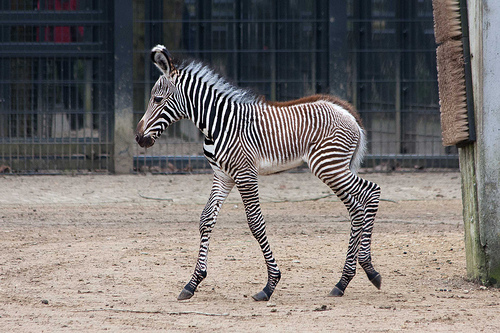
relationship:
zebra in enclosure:
[135, 45, 380, 300] [5, 10, 495, 331]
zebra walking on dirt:
[136, 45, 381, 300] [0, 172, 498, 330]